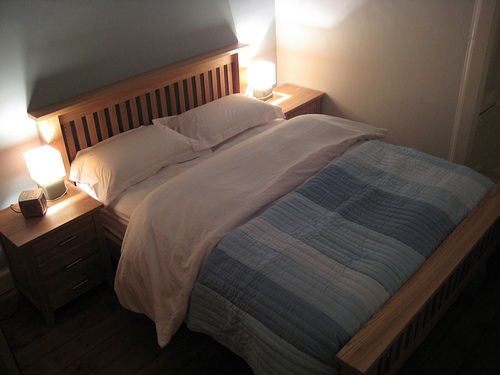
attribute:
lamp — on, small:
[33, 148, 66, 206]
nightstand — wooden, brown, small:
[31, 216, 117, 306]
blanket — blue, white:
[256, 209, 433, 305]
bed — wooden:
[65, 111, 445, 334]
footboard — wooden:
[381, 250, 453, 350]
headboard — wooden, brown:
[45, 48, 264, 118]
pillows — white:
[115, 109, 254, 161]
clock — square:
[15, 189, 46, 215]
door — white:
[464, 15, 493, 175]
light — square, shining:
[245, 62, 290, 97]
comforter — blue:
[221, 177, 436, 324]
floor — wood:
[34, 316, 200, 374]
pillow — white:
[96, 135, 187, 179]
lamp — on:
[247, 58, 291, 101]